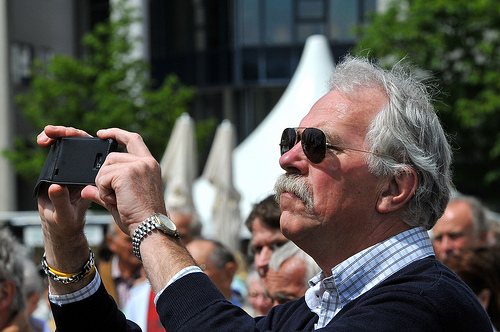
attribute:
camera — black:
[31, 134, 115, 195]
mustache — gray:
[276, 176, 315, 211]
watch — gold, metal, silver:
[129, 213, 180, 258]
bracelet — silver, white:
[43, 247, 97, 285]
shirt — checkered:
[306, 227, 432, 326]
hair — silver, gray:
[329, 53, 455, 231]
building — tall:
[144, 1, 414, 140]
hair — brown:
[244, 193, 283, 239]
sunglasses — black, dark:
[280, 125, 404, 168]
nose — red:
[279, 141, 310, 176]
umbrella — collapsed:
[160, 113, 195, 212]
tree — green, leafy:
[354, 0, 499, 213]